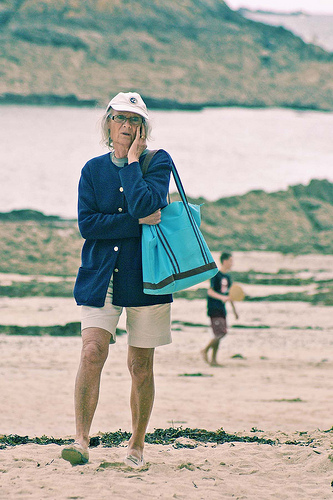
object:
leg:
[71, 282, 123, 450]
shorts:
[77, 269, 173, 349]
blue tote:
[135, 141, 220, 294]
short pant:
[79, 261, 171, 349]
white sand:
[2, 271, 332, 498]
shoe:
[59, 443, 88, 464]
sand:
[2, 439, 329, 497]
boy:
[199, 250, 238, 366]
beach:
[0, 252, 333, 498]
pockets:
[70, 259, 155, 307]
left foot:
[118, 437, 148, 468]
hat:
[88, 73, 172, 128]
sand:
[63, 456, 173, 488]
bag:
[140, 148, 218, 294]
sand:
[2, 253, 332, 499]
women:
[60, 90, 174, 467]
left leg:
[119, 264, 173, 473]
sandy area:
[0, 251, 332, 498]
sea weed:
[0, 425, 306, 453]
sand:
[0, 337, 322, 425]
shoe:
[109, 448, 157, 473]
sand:
[206, 462, 312, 486]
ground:
[15, 471, 328, 499]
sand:
[249, 382, 279, 413]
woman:
[78, 75, 190, 218]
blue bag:
[134, 194, 222, 302]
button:
[117, 181, 130, 196]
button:
[117, 201, 124, 215]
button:
[111, 242, 123, 251]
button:
[112, 264, 117, 278]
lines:
[133, 193, 222, 288]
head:
[86, 76, 182, 177]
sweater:
[72, 147, 173, 309]